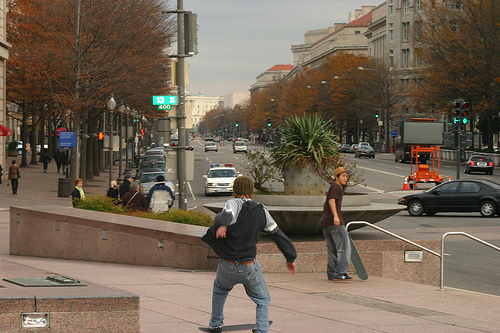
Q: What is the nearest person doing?
A: Skating.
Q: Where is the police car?
A: On the street.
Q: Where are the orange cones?
A: Behind the black car.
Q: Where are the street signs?
A: On the pole.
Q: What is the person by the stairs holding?
A: Skateboard.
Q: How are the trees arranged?
A: Rows.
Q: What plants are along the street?
A: Trees.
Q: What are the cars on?
A: A street.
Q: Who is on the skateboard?
A: A man.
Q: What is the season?
A: Autumn.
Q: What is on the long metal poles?
A: Lights.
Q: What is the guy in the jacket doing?
A: Skateboarding.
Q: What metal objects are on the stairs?
A: Rails.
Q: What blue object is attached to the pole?
A: A sign.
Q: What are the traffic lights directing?
A: The cars.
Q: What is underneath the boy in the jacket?
A: A skateboard.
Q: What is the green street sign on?
A: A pole.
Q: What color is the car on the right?
A: Black.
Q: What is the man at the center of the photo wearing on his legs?
A: Jeans.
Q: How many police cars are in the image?
A: One.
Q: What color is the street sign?
A: Green.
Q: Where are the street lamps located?
A: On the left.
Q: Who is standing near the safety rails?
A: A young man.